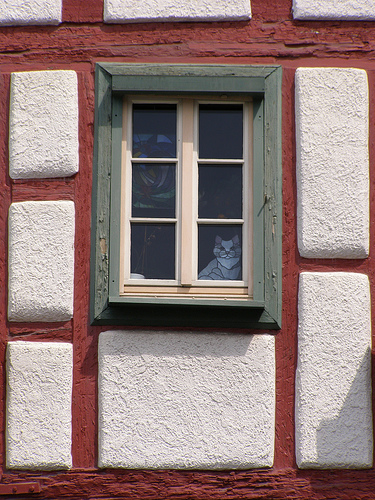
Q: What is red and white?
A: The wall.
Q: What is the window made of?
A: Glass.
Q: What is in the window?
A: A cat.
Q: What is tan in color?
A: The frame of window.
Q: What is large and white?
A: Block of building.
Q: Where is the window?
A: On building.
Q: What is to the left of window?
A: A block.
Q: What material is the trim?
A: Wood.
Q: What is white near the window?
A: A block.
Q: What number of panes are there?
A: Six.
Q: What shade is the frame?
A: Green.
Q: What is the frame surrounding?
A: A window.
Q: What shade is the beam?
A: Red.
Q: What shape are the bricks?
A: Rectangles.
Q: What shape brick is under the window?
A: Square.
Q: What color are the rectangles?
A: White.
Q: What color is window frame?
A: Green.